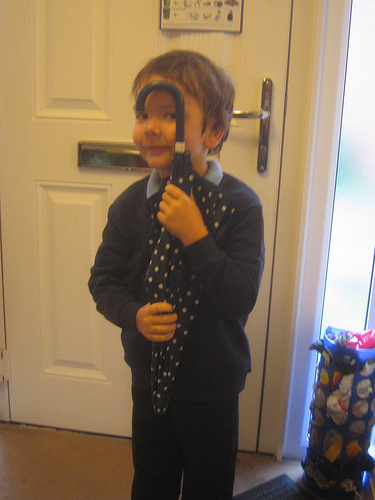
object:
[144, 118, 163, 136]
nose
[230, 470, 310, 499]
rug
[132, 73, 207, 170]
face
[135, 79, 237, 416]
umbrella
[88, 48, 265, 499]
boy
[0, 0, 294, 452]
door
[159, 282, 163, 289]
dot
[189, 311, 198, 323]
dot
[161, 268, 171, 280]
dot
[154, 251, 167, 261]
dot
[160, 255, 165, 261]
dot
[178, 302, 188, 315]
dot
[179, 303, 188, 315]
dot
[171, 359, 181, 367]
dot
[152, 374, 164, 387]
dot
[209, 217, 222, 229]
dot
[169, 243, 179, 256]
dot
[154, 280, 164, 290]
dot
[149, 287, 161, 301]
dot